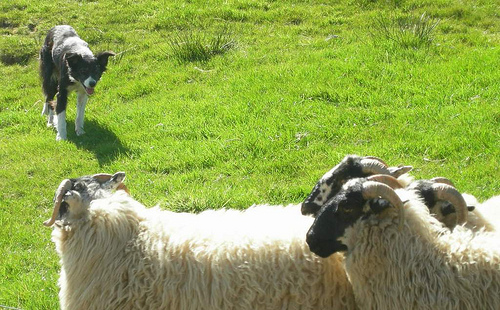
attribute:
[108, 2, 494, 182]
field — grassy, green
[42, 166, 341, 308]
sheep — standing, white, black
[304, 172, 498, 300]
sheep — black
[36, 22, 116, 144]
sheep dog — black, white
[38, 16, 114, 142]
dog — black , white 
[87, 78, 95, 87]
nose — black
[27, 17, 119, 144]
dog — white, black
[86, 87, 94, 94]
tongue — pink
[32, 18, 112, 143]
dog — black, white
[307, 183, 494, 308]
sheep — standing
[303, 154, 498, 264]
sheep — standing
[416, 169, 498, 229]
sheep — standing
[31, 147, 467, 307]
sheep — white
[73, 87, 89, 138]
leg — white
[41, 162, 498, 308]
fur — wooly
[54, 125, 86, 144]
paws — white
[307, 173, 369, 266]
faces — black